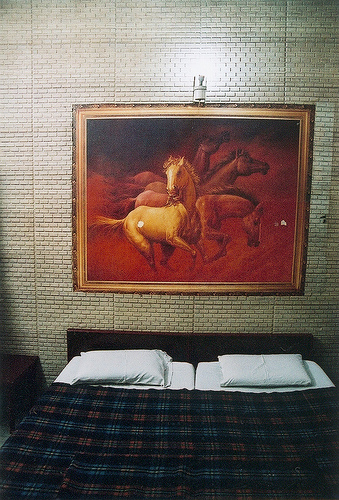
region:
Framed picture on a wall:
[68, 104, 306, 300]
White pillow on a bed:
[218, 354, 308, 386]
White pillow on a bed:
[79, 348, 171, 382]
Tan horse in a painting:
[94, 158, 201, 270]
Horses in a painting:
[101, 130, 270, 268]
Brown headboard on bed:
[64, 326, 317, 360]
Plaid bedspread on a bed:
[0, 381, 337, 497]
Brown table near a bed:
[1, 350, 38, 423]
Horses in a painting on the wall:
[105, 133, 270, 266]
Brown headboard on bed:
[58, 325, 324, 362]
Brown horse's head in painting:
[244, 196, 260, 248]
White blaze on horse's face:
[167, 168, 175, 190]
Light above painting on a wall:
[186, 70, 214, 101]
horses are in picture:
[114, 155, 250, 270]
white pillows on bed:
[75, 346, 317, 385]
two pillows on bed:
[76, 340, 325, 385]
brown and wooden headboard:
[60, 328, 306, 351]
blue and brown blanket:
[36, 385, 336, 487]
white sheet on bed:
[145, 345, 208, 397]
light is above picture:
[187, 64, 214, 100]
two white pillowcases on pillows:
[80, 338, 305, 397]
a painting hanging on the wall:
[73, 101, 314, 292]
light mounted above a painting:
[189, 71, 206, 101]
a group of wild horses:
[89, 131, 267, 276]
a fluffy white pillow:
[72, 344, 171, 386]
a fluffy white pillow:
[215, 352, 311, 389]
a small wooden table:
[0, 353, 42, 434]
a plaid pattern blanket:
[0, 384, 335, 496]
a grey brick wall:
[2, 0, 335, 382]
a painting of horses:
[68, 104, 308, 294]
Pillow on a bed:
[75, 342, 169, 390]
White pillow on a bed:
[73, 348, 165, 389]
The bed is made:
[11, 298, 324, 488]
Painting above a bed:
[64, 96, 320, 386]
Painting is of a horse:
[74, 99, 308, 297]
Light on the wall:
[188, 63, 210, 104]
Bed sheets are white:
[178, 366, 188, 381]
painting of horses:
[71, 98, 304, 290]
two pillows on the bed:
[71, 342, 307, 386]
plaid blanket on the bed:
[2, 381, 338, 499]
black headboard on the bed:
[69, 330, 311, 370]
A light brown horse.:
[87, 153, 208, 273]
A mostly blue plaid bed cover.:
[0, 384, 338, 498]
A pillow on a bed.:
[70, 343, 171, 405]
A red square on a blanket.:
[86, 408, 99, 416]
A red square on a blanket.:
[95, 392, 106, 397]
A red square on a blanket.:
[39, 403, 53, 413]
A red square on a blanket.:
[25, 430, 42, 442]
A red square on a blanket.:
[12, 458, 22, 475]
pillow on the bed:
[91, 347, 172, 380]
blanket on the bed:
[123, 378, 200, 412]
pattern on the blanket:
[126, 418, 201, 456]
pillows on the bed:
[106, 353, 268, 383]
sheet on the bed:
[179, 367, 194, 378]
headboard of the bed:
[143, 328, 198, 353]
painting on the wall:
[76, 13, 305, 291]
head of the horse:
[168, 156, 193, 196]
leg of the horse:
[174, 241, 203, 265]